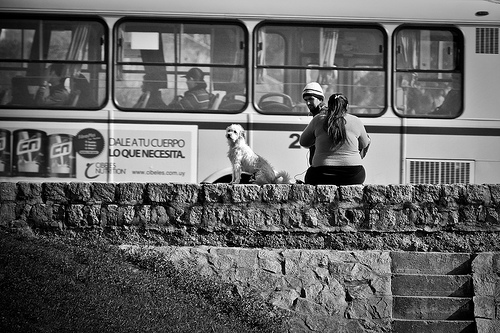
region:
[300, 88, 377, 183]
woman with dark hair sitting on wall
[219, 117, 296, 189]
white dog sitting on wall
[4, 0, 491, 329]
clear sunny daytime scene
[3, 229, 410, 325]
grassy slope next to wall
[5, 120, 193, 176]
Spanish advertising sign on bus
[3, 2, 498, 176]
white bus next to wall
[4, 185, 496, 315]
grey rocky wall with steps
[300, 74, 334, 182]
man in knit cap standing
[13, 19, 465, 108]
people riding the bus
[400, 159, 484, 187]
vent on side of white bus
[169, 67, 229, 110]
man sitting in a bus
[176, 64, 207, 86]
dark colored baseball cap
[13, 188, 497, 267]
brick wall next to the bus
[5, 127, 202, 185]
advertisement on a bus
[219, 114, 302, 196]
dog sitting on the brick wall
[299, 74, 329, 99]
beanie hat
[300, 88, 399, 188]
woman sitting on the brick wall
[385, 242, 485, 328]
steps leading to the brick wall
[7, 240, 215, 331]
grass next to the wall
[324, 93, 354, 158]
long and brown hair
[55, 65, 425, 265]
Black and white picture.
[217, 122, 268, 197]
one dog is seen.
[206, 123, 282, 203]
dog is sitting on wall.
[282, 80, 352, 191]
two people are outside the bus.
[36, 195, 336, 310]
stone wall is seen.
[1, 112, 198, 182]
advertisement in bus wall.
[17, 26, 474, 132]
windows are closed in bus.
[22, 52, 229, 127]
people are sitting in the bus.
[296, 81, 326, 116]
man is wearing the cap in head.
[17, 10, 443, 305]
A black and white picture.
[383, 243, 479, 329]
Concrete steps going up the wall.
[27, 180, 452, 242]
A rock wall.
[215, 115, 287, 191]
A large light colored dog.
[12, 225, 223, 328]
A grassy area.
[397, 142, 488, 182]
A vent on the side of a bus.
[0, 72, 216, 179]
Advertisement on the side of a bus.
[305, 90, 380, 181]
A woman with long dark hair.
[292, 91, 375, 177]
A woman in a light colored shirt.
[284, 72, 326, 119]
A man with a hat.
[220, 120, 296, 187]
dog sitting on a stone wall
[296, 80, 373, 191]
two people near a stone wall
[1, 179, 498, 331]
a stone wall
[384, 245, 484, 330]
stairs leading to a roadway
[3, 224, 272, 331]
mound of grass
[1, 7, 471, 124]
windows on the side of a bus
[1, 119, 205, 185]
an ad on the side of a bus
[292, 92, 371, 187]
a woman sitting on a stone wall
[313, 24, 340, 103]
a curtain in a bus window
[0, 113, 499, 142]
striping on the bus's side